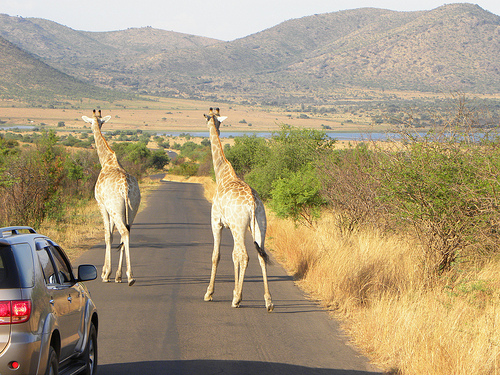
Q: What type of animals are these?
A: Giraffe.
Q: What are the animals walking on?
A: Street.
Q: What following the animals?
A: Car.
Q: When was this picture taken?
A: Daytime.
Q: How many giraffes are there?
A: 2.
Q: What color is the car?
A: Silver.